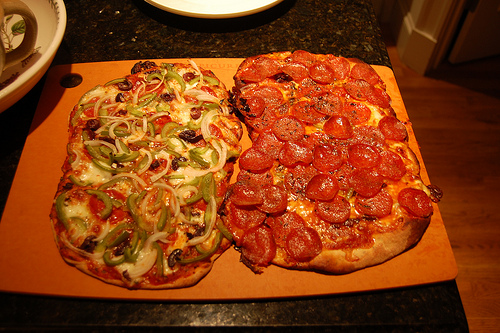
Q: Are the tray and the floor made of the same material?
A: Yes, both the tray and the floor are made of wood.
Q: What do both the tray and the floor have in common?
A: The material, both the tray and the floor are wooden.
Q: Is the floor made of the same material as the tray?
A: Yes, both the floor and the tray are made of wood.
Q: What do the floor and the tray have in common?
A: The material, both the floor and the tray are wooden.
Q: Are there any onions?
A: Yes, there is an onion.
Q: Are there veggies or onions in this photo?
A: Yes, there is an onion.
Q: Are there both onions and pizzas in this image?
A: Yes, there are both an onion and a pizza.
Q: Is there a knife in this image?
A: No, there are no knives.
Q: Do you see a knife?
A: No, there are no knives.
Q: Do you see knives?
A: No, there are no knives.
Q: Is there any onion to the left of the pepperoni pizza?
A: Yes, there is an onion to the left of the pizza.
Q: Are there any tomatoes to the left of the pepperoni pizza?
A: No, there is an onion to the left of the pizza.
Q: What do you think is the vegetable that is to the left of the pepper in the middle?
A: The vegetable is an onion.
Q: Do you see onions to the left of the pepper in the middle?
A: Yes, there is an onion to the left of the pepper.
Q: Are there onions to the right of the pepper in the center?
A: No, the onion is to the left of the pepper.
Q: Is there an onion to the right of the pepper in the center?
A: No, the onion is to the left of the pepper.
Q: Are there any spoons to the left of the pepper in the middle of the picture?
A: No, there is an onion to the left of the pepper.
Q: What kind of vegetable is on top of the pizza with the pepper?
A: The vegetable is an onion.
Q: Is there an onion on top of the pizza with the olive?
A: Yes, there is an onion on top of the pizza.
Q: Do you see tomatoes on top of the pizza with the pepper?
A: No, there is an onion on top of the pizza.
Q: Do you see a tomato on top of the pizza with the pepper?
A: No, there is an onion on top of the pizza.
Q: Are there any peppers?
A: Yes, there is a pepper.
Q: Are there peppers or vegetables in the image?
A: Yes, there is a pepper.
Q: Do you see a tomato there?
A: No, there are no tomatoes.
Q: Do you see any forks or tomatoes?
A: No, there are no tomatoes or forks.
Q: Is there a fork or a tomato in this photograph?
A: No, there are no tomatoes or forks.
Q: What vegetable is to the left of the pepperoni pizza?
A: The vegetable is a pepper.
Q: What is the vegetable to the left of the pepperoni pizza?
A: The vegetable is a pepper.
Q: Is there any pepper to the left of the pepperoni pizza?
A: Yes, there is a pepper to the left of the pizza.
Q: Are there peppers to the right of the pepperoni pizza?
A: No, the pepper is to the left of the pizza.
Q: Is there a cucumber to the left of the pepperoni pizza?
A: No, there is a pepper to the left of the pizza.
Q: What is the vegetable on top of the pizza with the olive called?
A: The vegetable is a pepper.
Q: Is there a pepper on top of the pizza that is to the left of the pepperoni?
A: Yes, there is a pepper on top of the pizza.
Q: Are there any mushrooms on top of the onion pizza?
A: No, there is a pepper on top of the pizza.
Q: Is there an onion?
A: Yes, there is an onion.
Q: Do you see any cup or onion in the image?
A: Yes, there is an onion.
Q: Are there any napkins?
A: No, there are no napkins.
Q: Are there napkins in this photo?
A: No, there are no napkins.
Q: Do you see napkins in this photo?
A: No, there are no napkins.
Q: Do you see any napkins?
A: No, there are no napkins.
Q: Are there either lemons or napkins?
A: No, there are no napkins or lemons.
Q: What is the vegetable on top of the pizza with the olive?
A: The vegetable is an onion.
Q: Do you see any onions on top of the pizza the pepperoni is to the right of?
A: Yes, there is an onion on top of the pizza.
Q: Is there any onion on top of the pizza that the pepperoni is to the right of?
A: Yes, there is an onion on top of the pizza.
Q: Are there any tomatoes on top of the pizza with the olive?
A: No, there is an onion on top of the pizza.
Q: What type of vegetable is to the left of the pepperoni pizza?
A: The vegetable is an onion.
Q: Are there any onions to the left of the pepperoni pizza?
A: Yes, there is an onion to the left of the pizza.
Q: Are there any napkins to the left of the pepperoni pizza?
A: No, there is an onion to the left of the pizza.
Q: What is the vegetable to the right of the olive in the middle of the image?
A: The vegetable is an onion.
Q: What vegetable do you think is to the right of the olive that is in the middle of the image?
A: The vegetable is an onion.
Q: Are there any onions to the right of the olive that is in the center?
A: Yes, there is an onion to the right of the olive.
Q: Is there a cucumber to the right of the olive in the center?
A: No, there is an onion to the right of the olive.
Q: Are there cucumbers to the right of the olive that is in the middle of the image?
A: No, there is an onion to the right of the olive.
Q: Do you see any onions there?
A: Yes, there is an onion.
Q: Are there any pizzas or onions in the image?
A: Yes, there is an onion.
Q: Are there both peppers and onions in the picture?
A: Yes, there are both an onion and a pepper.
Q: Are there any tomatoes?
A: No, there are no tomatoes.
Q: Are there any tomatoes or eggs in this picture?
A: No, there are no tomatoes or eggs.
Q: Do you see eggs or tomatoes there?
A: No, there are no tomatoes or eggs.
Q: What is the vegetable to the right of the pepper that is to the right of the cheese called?
A: The vegetable is an onion.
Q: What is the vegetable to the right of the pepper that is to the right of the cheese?
A: The vegetable is an onion.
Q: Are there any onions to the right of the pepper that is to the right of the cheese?
A: Yes, there is an onion to the right of the pepper.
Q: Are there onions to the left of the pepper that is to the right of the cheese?
A: No, the onion is to the right of the pepper.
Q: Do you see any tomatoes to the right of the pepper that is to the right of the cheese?
A: No, there is an onion to the right of the pepper.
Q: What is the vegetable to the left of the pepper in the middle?
A: The vegetable is an onion.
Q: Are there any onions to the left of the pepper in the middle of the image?
A: Yes, there is an onion to the left of the pepper.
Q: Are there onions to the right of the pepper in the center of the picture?
A: No, the onion is to the left of the pepper.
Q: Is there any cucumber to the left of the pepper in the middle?
A: No, there is an onion to the left of the pepper.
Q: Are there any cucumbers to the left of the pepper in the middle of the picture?
A: No, there is an onion to the left of the pepper.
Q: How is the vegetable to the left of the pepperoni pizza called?
A: The vegetable is an onion.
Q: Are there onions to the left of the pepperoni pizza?
A: Yes, there is an onion to the left of the pizza.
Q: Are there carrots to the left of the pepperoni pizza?
A: No, there is an onion to the left of the pizza.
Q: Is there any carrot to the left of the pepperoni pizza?
A: No, there is an onion to the left of the pizza.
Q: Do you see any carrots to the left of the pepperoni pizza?
A: No, there is an onion to the left of the pizza.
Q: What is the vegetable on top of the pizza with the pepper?
A: The vegetable is an onion.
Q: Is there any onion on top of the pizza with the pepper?
A: Yes, there is an onion on top of the pizza.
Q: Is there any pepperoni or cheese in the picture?
A: Yes, there is pepperoni.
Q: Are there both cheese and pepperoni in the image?
A: Yes, there are both pepperoni and cheese.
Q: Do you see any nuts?
A: No, there are no nuts.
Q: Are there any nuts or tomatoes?
A: No, there are no nuts or tomatoes.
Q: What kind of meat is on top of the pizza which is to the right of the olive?
A: The meat is pepperoni.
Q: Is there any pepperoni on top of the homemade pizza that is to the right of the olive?
A: Yes, there is pepperoni on top of the pizza.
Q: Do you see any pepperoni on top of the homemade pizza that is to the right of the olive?
A: Yes, there is pepperoni on top of the pizza.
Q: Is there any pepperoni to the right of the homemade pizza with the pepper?
A: Yes, there is pepperoni to the right of the pizza.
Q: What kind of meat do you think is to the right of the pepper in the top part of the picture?
A: The meat is pepperoni.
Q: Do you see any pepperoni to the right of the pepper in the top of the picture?
A: Yes, there is pepperoni to the right of the pepper.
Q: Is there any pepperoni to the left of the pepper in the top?
A: No, the pepperoni is to the right of the pepper.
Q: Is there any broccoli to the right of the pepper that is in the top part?
A: No, there is pepperoni to the right of the pepper.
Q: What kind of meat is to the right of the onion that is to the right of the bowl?
A: The meat is pepperoni.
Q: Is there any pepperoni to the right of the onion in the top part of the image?
A: Yes, there is pepperoni to the right of the onion.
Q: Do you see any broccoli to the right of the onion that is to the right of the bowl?
A: No, there is pepperoni to the right of the onion.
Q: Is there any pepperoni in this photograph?
A: Yes, there is pepperoni.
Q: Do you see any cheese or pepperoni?
A: Yes, there is pepperoni.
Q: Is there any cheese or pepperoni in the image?
A: Yes, there is pepperoni.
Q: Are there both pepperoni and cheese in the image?
A: Yes, there are both pepperoni and cheese.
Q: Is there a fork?
A: No, there are no forks.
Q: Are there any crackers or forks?
A: No, there are no forks or crackers.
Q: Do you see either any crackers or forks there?
A: No, there are no forks or crackers.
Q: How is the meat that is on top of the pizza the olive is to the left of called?
A: The meat is pepperoni.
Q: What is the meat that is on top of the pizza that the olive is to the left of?
A: The meat is pepperoni.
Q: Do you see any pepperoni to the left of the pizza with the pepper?
A: No, the pepperoni is to the right of the pizza.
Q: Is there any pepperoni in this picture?
A: Yes, there is pepperoni.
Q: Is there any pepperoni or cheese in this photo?
A: Yes, there is pepperoni.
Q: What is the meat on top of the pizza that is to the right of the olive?
A: The meat is pepperoni.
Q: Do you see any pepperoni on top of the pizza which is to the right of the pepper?
A: Yes, there is pepperoni on top of the pizza.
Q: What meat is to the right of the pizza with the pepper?
A: The meat is pepperoni.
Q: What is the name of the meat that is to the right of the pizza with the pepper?
A: The meat is pepperoni.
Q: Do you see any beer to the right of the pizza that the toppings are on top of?
A: No, there is pepperoni to the right of the pizza.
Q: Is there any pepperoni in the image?
A: Yes, there is pepperoni.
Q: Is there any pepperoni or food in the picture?
A: Yes, there is pepperoni.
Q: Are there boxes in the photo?
A: No, there are no boxes.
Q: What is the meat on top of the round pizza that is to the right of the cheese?
A: The meat is pepperoni.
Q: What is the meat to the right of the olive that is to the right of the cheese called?
A: The meat is pepperoni.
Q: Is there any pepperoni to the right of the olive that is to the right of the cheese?
A: Yes, there is pepperoni to the right of the olive.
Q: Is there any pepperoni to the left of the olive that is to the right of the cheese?
A: No, the pepperoni is to the right of the olive.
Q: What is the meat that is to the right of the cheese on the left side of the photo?
A: The meat is pepperoni.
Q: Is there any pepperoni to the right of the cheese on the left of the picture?
A: Yes, there is pepperoni to the right of the cheese.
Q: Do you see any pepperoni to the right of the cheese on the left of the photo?
A: Yes, there is pepperoni to the right of the cheese.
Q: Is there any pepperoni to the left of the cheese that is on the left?
A: No, the pepperoni is to the right of the cheese.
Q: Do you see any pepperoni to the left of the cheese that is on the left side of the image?
A: No, the pepperoni is to the right of the cheese.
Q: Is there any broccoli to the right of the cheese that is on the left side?
A: No, there is pepperoni to the right of the cheese.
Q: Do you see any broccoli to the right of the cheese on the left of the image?
A: No, there is pepperoni to the right of the cheese.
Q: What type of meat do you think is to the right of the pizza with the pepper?
A: The meat is pepperoni.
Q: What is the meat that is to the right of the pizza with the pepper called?
A: The meat is pepperoni.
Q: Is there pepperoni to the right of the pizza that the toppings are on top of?
A: Yes, there is pepperoni to the right of the pizza.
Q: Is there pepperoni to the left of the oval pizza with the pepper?
A: No, the pepperoni is to the right of the pizza.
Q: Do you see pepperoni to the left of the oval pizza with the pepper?
A: No, the pepperoni is to the right of the pizza.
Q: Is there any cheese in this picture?
A: Yes, there is cheese.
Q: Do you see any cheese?
A: Yes, there is cheese.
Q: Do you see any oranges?
A: No, there are no oranges.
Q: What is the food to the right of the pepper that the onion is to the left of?
A: The food is cheese.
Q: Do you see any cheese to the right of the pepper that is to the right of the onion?
A: Yes, there is cheese to the right of the pepper.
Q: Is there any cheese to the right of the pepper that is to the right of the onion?
A: Yes, there is cheese to the right of the pepper.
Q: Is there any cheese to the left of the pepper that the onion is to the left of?
A: No, the cheese is to the right of the pepper.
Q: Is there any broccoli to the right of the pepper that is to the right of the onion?
A: No, there is cheese to the right of the pepper.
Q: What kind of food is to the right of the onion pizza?
A: The food is cheese.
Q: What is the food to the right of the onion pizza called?
A: The food is cheese.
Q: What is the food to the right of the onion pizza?
A: The food is cheese.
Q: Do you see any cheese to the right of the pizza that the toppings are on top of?
A: Yes, there is cheese to the right of the pizza.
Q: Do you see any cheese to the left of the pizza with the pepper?
A: No, the cheese is to the right of the pizza.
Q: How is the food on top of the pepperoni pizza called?
A: The food is cheese.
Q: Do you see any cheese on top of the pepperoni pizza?
A: Yes, there is cheese on top of the pizza.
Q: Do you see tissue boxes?
A: No, there are no tissue boxes.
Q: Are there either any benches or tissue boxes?
A: No, there are no tissue boxes or benches.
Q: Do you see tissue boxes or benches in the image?
A: No, there are no tissue boxes or benches.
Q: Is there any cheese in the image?
A: Yes, there is cheese.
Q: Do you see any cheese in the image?
A: Yes, there is cheese.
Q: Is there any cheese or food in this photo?
A: Yes, there is cheese.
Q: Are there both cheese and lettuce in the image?
A: No, there is cheese but no lettuce.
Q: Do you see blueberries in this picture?
A: No, there are no blueberries.